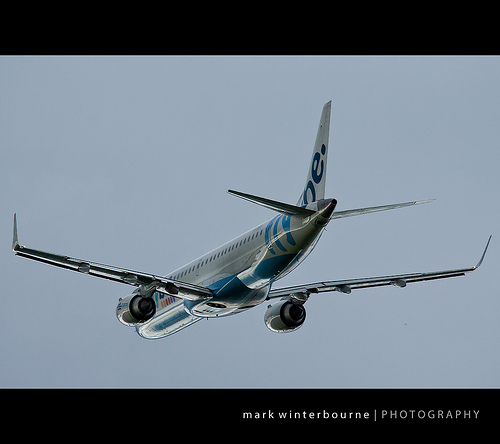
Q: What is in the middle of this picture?
A: A plane.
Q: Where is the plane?
A: In the sky.